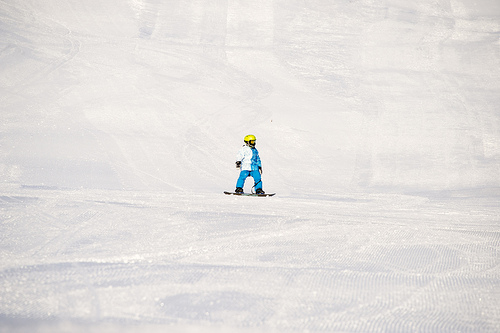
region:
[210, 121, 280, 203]
man snowboarding in the snow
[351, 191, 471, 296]
white snow on the ground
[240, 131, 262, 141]
yellow helmet on a snowboarder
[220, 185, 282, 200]
snowboard under a man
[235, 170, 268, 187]
blue snow pants on a man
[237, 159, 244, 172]
black glove on right hand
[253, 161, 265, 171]
black glove on left hand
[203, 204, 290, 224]
tracks in the snow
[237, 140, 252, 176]
white jacket on a snowboarder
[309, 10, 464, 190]
hill in the snow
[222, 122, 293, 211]
person wearing blue and white coat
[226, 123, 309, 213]
person wearing blue snowpants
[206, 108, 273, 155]
person with a yellow helmet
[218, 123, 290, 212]
person snow boarding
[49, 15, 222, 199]
white snow hill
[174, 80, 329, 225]
person snowboarding down hill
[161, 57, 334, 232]
snowboarding down big snow hill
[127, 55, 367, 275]
person resting at bottom of snow hill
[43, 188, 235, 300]
bottom of snow hill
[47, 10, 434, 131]
tracks from skiiers in a snow hill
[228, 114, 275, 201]
snow boarder in white snow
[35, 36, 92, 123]
white snow on hill side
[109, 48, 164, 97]
white snow on hill side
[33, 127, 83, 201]
white snow on hill side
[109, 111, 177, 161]
white snow on hill side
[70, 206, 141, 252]
white snow on hill side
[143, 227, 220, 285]
white snow on hill side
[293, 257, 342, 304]
white snow on hill side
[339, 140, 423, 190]
white snow on hill side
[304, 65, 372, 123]
white snow on hill side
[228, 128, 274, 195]
The boy is wearing a helmet.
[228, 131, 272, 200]
The boy is wearing a yellow helmet.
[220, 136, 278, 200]
The boy is on a snowboard.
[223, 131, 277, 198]
The boy is wearing a blue and white jacket.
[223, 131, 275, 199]
The boy is wearing blue pants.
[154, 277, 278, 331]
The snow in the forefront is white.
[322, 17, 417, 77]
The snow in the background is white.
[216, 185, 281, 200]
The boy's snowboard is black.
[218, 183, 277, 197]
The boy's snow boots are black.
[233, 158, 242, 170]
The boy's gloves are black.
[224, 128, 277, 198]
snowboarder in the middle of a snow field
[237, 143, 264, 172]
snowboarder wearing white and blue jacket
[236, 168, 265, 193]
snowboarder wearing blue pants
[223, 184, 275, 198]
snowboarder strapped to snowboard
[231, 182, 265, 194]
snowboarder wearing snowboard shoes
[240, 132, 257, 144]
snowboarder wearing yellow helmet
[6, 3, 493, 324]
snow is bright white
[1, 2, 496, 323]
snow hill is flat and smooth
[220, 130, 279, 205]
snowboarder standing in middle of ski trail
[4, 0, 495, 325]
hill is freshly groomed